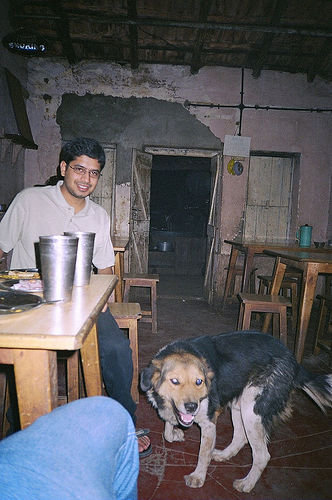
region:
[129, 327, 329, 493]
brown black and white dog standing near table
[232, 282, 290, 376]
wooden stool on floor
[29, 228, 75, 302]
tall silver metal cup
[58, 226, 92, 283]
tall silver metal cup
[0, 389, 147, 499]
leg of man wearing light blue pants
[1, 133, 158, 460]
man with black hair and glasses sitting at a table in restaurant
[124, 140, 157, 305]
brown and white door to small building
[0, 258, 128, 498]
light brown wooden table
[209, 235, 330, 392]
brown wooden tables in restaurant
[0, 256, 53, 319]
plates of food on table in restaurant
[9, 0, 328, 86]
Wood cross beam ceiling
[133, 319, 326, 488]
Black and white dog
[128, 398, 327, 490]
Cracked red floor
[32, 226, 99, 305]
Two metallic cups on wooden table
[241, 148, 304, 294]
Narrow wooden white door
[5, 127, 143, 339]
Man with glasses sitting at table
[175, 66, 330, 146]
Black piping along the wall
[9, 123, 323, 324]
Man sitting in a restaurant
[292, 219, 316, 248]
Small green pitcher on table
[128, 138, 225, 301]
Opened double doors leading to another room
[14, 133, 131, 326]
man sitting at table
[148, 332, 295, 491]
dog standing on floor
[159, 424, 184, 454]
bent paw above floor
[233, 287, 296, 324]
stool with square seat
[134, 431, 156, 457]
toes of foot in sandal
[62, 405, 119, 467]
knee of blue jeans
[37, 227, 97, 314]
two silver cups on table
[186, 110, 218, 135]
peeled paint on wall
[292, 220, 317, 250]
blue container on table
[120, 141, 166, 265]
open wood door of room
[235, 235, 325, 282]
Table is brown color.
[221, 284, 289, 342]
Stool is brown color.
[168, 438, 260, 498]
Floor is red color.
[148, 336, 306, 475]
Dog is black and brown color.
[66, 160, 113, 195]
man is wearing eyeglass.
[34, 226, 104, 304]
two glass are in table.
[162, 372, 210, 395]
eyes are yellow color.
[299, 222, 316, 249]
Jug is green color.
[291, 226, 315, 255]
Jug is in table.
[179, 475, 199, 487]
edge of a paw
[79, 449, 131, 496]
part of a trouser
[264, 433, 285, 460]
part of a floor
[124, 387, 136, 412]
part of a trouser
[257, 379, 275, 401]
part of a thigh